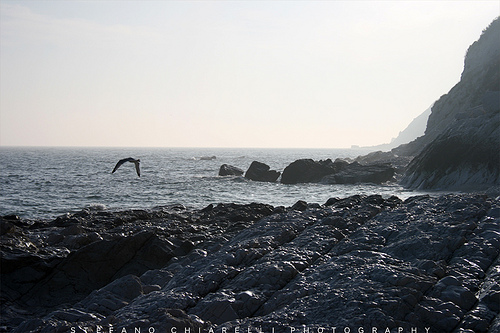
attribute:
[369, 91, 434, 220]
cliff — misty, distant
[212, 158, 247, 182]
rock — strange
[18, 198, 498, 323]
rocks — black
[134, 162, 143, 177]
wing — the right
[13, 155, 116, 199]
water — choppy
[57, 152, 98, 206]
water — dark, blue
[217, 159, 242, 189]
boulder — large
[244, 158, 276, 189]
boulder — large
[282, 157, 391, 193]
boulder — large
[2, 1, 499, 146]
sky — hazy, pink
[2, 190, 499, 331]
beach — rocky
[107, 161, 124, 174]
wing — the left